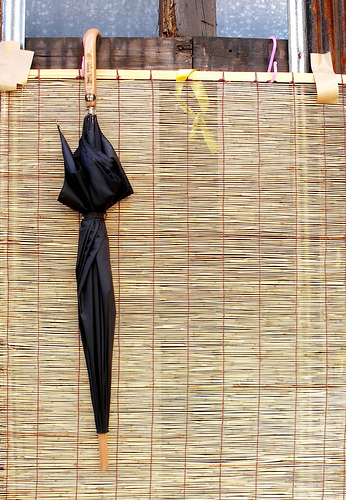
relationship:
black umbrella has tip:
[55, 26, 134, 472] [97, 433, 110, 471]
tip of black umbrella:
[98, 431, 108, 470] [55, 26, 134, 472]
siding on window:
[0, 0, 28, 57] [22, 0, 321, 74]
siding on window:
[287, 1, 307, 73] [215, 0, 289, 40]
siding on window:
[287, 1, 307, 73] [25, 1, 159, 37]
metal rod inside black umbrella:
[87, 105, 94, 113] [55, 26, 134, 472]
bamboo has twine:
[0, 61, 335, 493] [149, 86, 157, 497]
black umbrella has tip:
[55, 26, 134, 472] [91, 431, 109, 473]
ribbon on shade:
[173, 65, 222, 152] [1, 67, 345, 499]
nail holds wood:
[229, 47, 234, 53] [193, 37, 268, 72]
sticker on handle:
[82, 91, 98, 101] [79, 25, 102, 113]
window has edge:
[25, 0, 288, 37] [233, 33, 249, 44]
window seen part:
[25, 0, 288, 37] [233, 8, 246, 24]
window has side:
[25, 5, 292, 52] [246, 14, 254, 22]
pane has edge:
[28, 0, 159, 38] [212, 353, 223, 368]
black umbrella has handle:
[55, 26, 134, 472] [81, 25, 105, 111]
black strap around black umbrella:
[78, 209, 106, 221] [52, 6, 128, 474]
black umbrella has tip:
[55, 26, 134, 472] [95, 431, 111, 475]